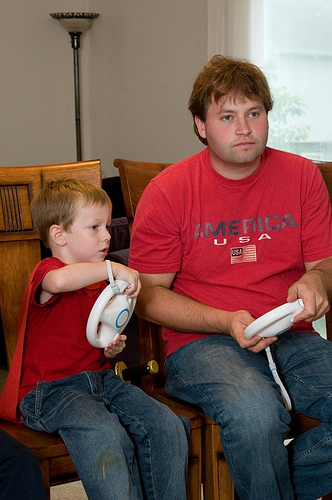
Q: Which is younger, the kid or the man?
A: The kid is younger than the man.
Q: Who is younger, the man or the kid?
A: The kid is younger than the man.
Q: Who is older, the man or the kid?
A: The man is older than the kid.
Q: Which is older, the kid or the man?
A: The man is older than the kid.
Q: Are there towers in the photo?
A: No, there are no towers.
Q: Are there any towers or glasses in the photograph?
A: No, there are no towers or glasses.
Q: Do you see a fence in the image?
A: No, there are no fences.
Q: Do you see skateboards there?
A: No, there are no skateboards.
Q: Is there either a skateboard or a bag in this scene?
A: No, there are no skateboards or bags.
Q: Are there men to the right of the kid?
A: Yes, there is a man to the right of the kid.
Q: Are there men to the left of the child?
A: No, the man is to the right of the child.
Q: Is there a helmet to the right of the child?
A: No, there is a man to the right of the child.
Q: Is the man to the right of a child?
A: Yes, the man is to the right of a child.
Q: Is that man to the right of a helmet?
A: No, the man is to the right of a child.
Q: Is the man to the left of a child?
A: No, the man is to the right of a child.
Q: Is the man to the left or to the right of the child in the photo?
A: The man is to the right of the child.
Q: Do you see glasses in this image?
A: No, there are no glasses.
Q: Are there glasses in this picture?
A: No, there are no glasses.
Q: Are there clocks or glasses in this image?
A: No, there are no glasses or clocks.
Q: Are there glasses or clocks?
A: No, there are no glasses or clocks.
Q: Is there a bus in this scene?
A: No, there are no buses.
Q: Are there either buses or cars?
A: No, there are no buses or cars.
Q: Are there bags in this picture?
A: No, there are no bags.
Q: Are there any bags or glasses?
A: No, there are no bags or glasses.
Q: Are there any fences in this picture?
A: No, there are no fences.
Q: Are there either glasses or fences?
A: No, there are no fences or glasses.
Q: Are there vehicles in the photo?
A: No, there are no vehicles.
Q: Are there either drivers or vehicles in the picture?
A: No, there are no vehicles or drivers.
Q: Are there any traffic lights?
A: No, there are no traffic lights.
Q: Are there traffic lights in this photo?
A: No, there are no traffic lights.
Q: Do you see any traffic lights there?
A: No, there are no traffic lights.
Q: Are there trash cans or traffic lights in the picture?
A: No, there are no traffic lights or trash cans.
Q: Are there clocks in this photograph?
A: No, there are no clocks.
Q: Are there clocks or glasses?
A: No, there are no clocks or glasses.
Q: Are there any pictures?
A: No, there are no pictures.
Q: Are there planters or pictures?
A: No, there are no pictures or planters.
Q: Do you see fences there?
A: No, there are no fences.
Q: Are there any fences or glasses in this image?
A: No, there are no fences or glasses.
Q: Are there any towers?
A: No, there are no towers.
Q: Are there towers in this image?
A: No, there are no towers.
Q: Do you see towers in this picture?
A: No, there are no towers.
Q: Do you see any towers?
A: No, there are no towers.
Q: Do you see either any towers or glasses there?
A: No, there are no towers or glasses.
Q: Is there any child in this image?
A: Yes, there is a child.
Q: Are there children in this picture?
A: Yes, there is a child.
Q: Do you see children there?
A: Yes, there is a child.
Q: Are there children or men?
A: Yes, there is a child.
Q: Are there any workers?
A: No, there are no workers.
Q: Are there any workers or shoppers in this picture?
A: No, there are no workers or shoppers.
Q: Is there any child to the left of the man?
A: Yes, there is a child to the left of the man.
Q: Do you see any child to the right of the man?
A: No, the child is to the left of the man.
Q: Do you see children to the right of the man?
A: No, the child is to the left of the man.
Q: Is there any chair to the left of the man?
A: No, there is a child to the left of the man.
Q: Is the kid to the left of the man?
A: Yes, the kid is to the left of the man.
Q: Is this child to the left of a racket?
A: No, the child is to the left of the man.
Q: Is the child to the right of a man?
A: No, the child is to the left of a man.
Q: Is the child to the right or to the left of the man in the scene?
A: The child is to the left of the man.